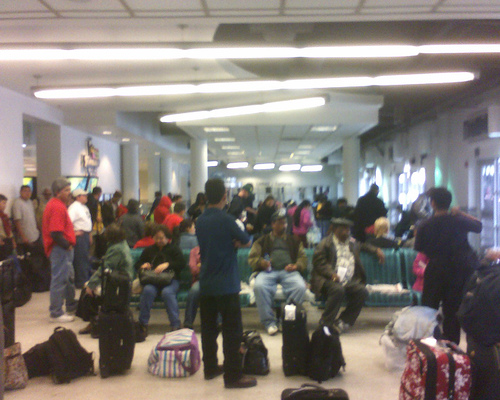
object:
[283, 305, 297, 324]
tag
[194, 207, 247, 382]
suit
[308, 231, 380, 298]
jacket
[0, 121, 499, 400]
transit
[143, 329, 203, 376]
backpack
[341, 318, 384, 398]
ground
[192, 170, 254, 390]
man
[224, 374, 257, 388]
shoes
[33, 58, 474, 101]
light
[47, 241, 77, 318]
jeans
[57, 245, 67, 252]
hand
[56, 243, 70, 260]
pocket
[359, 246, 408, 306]
green bench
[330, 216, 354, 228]
brown hat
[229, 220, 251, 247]
arms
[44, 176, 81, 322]
man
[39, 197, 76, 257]
red shirt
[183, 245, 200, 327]
people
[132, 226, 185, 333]
people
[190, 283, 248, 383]
pants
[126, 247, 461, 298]
bench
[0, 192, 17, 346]
people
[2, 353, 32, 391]
bag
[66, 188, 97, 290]
person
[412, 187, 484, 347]
person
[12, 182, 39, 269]
person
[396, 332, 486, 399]
suitcase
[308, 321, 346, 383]
luggage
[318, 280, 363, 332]
trousers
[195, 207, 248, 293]
blue shirt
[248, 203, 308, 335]
man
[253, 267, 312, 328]
jeans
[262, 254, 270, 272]
water bottle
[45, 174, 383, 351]
group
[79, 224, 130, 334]
people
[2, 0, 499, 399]
airport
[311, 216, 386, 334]
man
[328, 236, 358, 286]
shirt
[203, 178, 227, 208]
hair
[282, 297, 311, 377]
suitcase